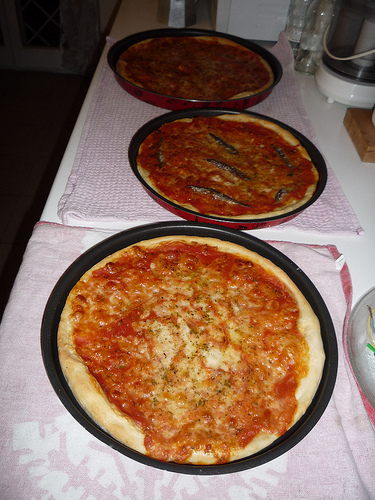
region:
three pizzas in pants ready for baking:
[36, 26, 336, 477]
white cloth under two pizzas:
[56, 31, 364, 244]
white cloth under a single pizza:
[0, 219, 367, 492]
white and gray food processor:
[312, 0, 370, 113]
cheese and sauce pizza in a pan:
[40, 218, 340, 474]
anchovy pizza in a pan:
[126, 100, 327, 227]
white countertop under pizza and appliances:
[278, 50, 372, 293]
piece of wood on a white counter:
[343, 103, 370, 162]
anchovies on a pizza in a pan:
[187, 127, 256, 211]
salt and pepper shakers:
[283, 0, 334, 78]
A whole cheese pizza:
[52, 231, 328, 468]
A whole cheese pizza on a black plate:
[37, 217, 340, 480]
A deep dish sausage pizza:
[132, 107, 323, 222]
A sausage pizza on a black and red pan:
[123, 103, 330, 233]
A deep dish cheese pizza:
[113, 33, 277, 103]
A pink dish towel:
[1, 218, 373, 496]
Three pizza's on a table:
[39, 25, 341, 476]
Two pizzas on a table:
[103, 22, 329, 230]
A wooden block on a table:
[340, 105, 374, 163]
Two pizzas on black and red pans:
[102, 25, 329, 232]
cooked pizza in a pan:
[24, 212, 342, 476]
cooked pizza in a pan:
[119, 92, 329, 232]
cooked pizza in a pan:
[100, 24, 282, 115]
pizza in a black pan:
[122, 107, 329, 229]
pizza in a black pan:
[24, 216, 355, 482]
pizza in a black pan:
[96, 20, 287, 114]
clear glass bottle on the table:
[288, 0, 337, 79]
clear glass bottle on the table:
[281, 1, 313, 61]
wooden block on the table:
[338, 104, 373, 165]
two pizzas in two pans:
[67, 16, 343, 231]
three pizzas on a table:
[34, 31, 339, 478]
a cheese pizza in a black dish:
[41, 225, 337, 477]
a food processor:
[322, 15, 372, 105]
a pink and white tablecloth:
[20, 443, 108, 489]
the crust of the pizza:
[70, 380, 101, 406]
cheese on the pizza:
[156, 328, 213, 363]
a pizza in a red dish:
[129, 106, 328, 222]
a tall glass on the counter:
[296, 0, 331, 75]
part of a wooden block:
[342, 106, 374, 161]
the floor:
[9, 82, 52, 139]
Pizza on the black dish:
[48, 224, 337, 474]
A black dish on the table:
[39, 221, 338, 475]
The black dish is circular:
[38, 221, 340, 474]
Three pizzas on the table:
[39, 26, 342, 476]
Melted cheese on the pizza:
[74, 244, 307, 459]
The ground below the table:
[0, 69, 93, 315]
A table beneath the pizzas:
[2, 0, 374, 499]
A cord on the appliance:
[322, 26, 373, 60]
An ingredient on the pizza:
[190, 185, 284, 206]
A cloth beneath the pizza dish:
[0, 220, 374, 495]